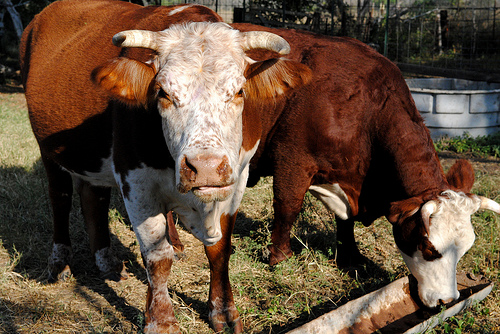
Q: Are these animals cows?
A: Yes, all the animals are cows.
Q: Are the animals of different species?
A: No, all the animals are cows.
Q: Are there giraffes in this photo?
A: No, there are no giraffes.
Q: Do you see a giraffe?
A: No, there are no giraffes.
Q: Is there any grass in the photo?
A: Yes, there is grass.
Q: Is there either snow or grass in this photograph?
A: Yes, there is grass.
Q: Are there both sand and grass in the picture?
A: No, there is grass but no sand.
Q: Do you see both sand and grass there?
A: No, there is grass but no sand.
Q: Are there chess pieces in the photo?
A: No, there are no chess pieces.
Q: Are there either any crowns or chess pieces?
A: No, there are no chess pieces or crowns.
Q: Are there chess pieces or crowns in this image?
A: No, there are no chess pieces or crowns.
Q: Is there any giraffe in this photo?
A: No, there are no giraffes.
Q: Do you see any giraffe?
A: No, there are no giraffes.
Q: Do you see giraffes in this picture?
A: No, there are no giraffes.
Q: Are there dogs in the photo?
A: No, there are no dogs.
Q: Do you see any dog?
A: No, there are no dogs.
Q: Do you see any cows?
A: Yes, there is a cow.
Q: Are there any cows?
A: Yes, there is a cow.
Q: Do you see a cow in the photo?
A: Yes, there is a cow.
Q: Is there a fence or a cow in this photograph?
A: Yes, there is a cow.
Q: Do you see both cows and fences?
A: Yes, there are both a cow and a fence.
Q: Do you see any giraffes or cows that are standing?
A: Yes, the cow is standing.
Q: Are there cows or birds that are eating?
A: Yes, the cow is eating.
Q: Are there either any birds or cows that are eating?
A: Yes, the cow is eating.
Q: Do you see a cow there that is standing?
A: Yes, there is a cow that is standing.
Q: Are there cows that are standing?
A: Yes, there is a cow that is standing.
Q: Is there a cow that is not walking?
A: Yes, there is a cow that is standing.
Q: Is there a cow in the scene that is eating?
A: Yes, there is a cow that is eating.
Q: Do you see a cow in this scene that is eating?
A: Yes, there is a cow that is eating.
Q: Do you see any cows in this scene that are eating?
A: Yes, there is a cow that is eating.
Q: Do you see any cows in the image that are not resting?
A: Yes, there is a cow that is eating .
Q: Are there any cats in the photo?
A: No, there are no cats.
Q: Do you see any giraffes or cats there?
A: No, there are no cats or giraffes.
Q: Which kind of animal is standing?
A: The animal is a cow.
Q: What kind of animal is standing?
A: The animal is a cow.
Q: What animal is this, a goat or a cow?
A: This is a cow.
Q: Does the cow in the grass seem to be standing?
A: Yes, the cow is standing.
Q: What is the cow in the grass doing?
A: The cow is standing.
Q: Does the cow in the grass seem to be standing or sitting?
A: The cow is standing.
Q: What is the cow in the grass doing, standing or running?
A: The cow is standing.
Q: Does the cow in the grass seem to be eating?
A: Yes, the cow is eating.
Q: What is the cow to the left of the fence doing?
A: The cow is eating.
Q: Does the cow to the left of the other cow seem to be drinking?
A: No, the cow is eating.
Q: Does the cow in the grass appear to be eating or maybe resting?
A: The cow is eating.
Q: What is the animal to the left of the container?
A: The animal is a cow.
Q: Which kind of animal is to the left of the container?
A: The animal is a cow.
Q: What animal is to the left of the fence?
A: The animal is a cow.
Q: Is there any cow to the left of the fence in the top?
A: Yes, there is a cow to the left of the fence.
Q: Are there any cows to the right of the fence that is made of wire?
A: No, the cow is to the left of the fence.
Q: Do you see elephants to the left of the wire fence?
A: No, there is a cow to the left of the fence.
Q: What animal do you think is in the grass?
A: The animal is a cow.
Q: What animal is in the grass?
A: The animal is a cow.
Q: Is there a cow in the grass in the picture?
A: Yes, there is a cow in the grass.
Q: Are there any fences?
A: Yes, there is a fence.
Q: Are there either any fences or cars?
A: Yes, there is a fence.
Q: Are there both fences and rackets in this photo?
A: No, there is a fence but no rackets.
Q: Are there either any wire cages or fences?
A: Yes, there is a wire fence.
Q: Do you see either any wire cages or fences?
A: Yes, there is a wire fence.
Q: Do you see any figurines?
A: No, there are no figurines.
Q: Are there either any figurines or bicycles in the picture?
A: No, there are no figurines or bicycles.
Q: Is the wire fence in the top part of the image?
A: Yes, the fence is in the top of the image.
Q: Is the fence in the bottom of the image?
A: No, the fence is in the top of the image.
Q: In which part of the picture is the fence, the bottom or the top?
A: The fence is in the top of the image.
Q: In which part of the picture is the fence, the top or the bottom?
A: The fence is in the top of the image.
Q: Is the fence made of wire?
A: Yes, the fence is made of wire.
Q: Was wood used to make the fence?
A: No, the fence is made of wire.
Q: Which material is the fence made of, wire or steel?
A: The fence is made of wire.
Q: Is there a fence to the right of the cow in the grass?
A: Yes, there is a fence to the right of the cow.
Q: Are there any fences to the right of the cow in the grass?
A: Yes, there is a fence to the right of the cow.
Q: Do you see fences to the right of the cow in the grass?
A: Yes, there is a fence to the right of the cow.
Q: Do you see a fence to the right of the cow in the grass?
A: Yes, there is a fence to the right of the cow.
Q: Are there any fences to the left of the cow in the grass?
A: No, the fence is to the right of the cow.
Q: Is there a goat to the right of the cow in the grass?
A: No, there is a fence to the right of the cow.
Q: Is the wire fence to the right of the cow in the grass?
A: Yes, the fence is to the right of the cow.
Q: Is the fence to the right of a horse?
A: No, the fence is to the right of the cow.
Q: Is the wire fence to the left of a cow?
A: No, the fence is to the right of a cow.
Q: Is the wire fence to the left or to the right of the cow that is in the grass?
A: The fence is to the right of the cow.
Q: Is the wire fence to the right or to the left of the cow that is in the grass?
A: The fence is to the right of the cow.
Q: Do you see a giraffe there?
A: No, there are no giraffes.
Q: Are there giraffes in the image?
A: No, there are no giraffes.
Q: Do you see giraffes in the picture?
A: No, there are no giraffes.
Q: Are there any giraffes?
A: No, there are no giraffes.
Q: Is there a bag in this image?
A: No, there are no bags.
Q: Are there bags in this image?
A: No, there are no bags.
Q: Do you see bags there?
A: No, there are no bags.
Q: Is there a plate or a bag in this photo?
A: No, there are no bags or plates.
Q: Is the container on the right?
A: Yes, the container is on the right of the image.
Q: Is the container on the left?
A: No, the container is on the right of the image.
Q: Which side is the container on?
A: The container is on the right of the image.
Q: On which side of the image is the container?
A: The container is on the right of the image.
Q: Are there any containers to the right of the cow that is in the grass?
A: Yes, there is a container to the right of the cow.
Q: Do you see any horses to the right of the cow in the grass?
A: No, there is a container to the right of the cow.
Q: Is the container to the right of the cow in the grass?
A: Yes, the container is to the right of the cow.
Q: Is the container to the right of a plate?
A: No, the container is to the right of the cow.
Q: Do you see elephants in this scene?
A: No, there are no elephants.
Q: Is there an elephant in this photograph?
A: No, there are no elephants.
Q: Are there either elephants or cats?
A: No, there are no elephants or cats.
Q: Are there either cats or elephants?
A: No, there are no elephants or cats.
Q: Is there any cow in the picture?
A: Yes, there is a cow.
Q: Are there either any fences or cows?
A: Yes, there is a cow.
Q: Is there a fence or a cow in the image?
A: Yes, there is a cow.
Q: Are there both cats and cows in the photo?
A: No, there is a cow but no cats.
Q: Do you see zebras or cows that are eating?
A: Yes, the cow is eating.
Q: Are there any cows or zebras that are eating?
A: Yes, the cow is eating.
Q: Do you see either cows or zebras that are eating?
A: Yes, the cow is eating.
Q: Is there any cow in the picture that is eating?
A: Yes, there is a cow that is eating.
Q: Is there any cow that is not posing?
A: Yes, there is a cow that is eating.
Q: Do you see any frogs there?
A: No, there are no frogs.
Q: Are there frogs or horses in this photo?
A: No, there are no frogs or horses.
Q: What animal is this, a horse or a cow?
A: This is a cow.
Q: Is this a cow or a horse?
A: This is a cow.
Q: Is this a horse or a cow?
A: This is a cow.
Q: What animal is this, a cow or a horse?
A: This is a cow.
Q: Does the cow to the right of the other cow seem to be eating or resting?
A: The cow is eating.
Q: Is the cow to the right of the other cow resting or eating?
A: The cow is eating.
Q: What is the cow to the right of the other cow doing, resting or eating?
A: The cow is eating.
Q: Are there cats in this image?
A: No, there are no cats.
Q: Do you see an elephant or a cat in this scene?
A: No, there are no cats or elephants.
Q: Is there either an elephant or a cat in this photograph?
A: No, there are no cats or elephants.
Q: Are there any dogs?
A: No, there are no dogs.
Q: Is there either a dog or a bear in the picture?
A: No, there are no dogs or bears.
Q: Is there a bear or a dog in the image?
A: No, there are no dogs or bears.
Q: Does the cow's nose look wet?
A: Yes, the nose is wet.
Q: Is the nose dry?
A: No, the nose is wet.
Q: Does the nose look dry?
A: No, the nose is wet.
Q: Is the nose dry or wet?
A: The nose is wet.